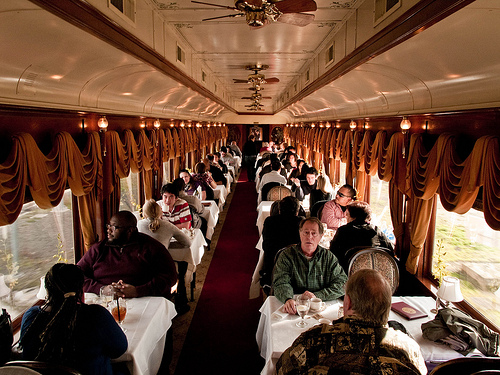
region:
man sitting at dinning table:
[72, 206, 178, 297]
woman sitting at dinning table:
[11, 261, 126, 371]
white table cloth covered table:
[12, 290, 173, 370]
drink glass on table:
[107, 292, 127, 327]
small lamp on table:
[435, 275, 462, 305]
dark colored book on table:
[390, 300, 425, 316]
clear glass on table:
[291, 290, 311, 325]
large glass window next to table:
[425, 190, 496, 330]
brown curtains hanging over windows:
[270, 125, 495, 270]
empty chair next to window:
[345, 243, 401, 296]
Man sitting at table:
[271, 225, 344, 300]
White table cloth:
[237, 206, 358, 252]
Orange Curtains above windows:
[357, 120, 494, 240]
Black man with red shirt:
[76, 225, 171, 295]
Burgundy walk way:
[206, 260, 232, 370]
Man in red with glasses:
[310, 180, 385, 231]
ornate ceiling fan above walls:
[230, 95, 370, 125]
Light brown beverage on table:
[95, 290, 176, 335]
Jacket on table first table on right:
[410, 265, 496, 360]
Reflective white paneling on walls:
[293, 83, 493, 118]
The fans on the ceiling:
[191, 1, 318, 123]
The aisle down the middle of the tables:
[176, 148, 274, 371]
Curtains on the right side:
[281, 118, 494, 240]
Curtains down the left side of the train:
[0, 118, 234, 223]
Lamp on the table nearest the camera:
[437, 272, 464, 320]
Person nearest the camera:
[276, 270, 452, 370]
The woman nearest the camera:
[7, 258, 127, 373]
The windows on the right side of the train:
[286, 143, 497, 339]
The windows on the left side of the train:
[3, 146, 215, 327]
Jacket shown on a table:
[414, 305, 498, 369]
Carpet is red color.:
[221, 221, 249, 299]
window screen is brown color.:
[19, 143, 121, 180]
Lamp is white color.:
[444, 276, 465, 312]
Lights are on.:
[83, 111, 238, 135]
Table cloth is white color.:
[106, 290, 160, 335]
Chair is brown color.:
[352, 248, 406, 283]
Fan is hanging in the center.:
[229, 63, 277, 115]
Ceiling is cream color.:
[159, 38, 244, 108]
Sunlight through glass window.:
[426, 202, 495, 322]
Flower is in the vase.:
[432, 240, 445, 310]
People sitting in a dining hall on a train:
[14, 93, 494, 371]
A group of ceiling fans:
[191, 0, 325, 116]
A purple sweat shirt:
[64, 234, 179, 302]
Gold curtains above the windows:
[3, 111, 233, 235]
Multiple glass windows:
[4, 151, 201, 320]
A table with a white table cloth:
[0, 271, 185, 370]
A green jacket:
[263, 242, 354, 325]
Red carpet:
[190, 151, 264, 372]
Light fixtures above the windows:
[31, 102, 431, 132]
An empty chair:
[346, 243, 407, 314]